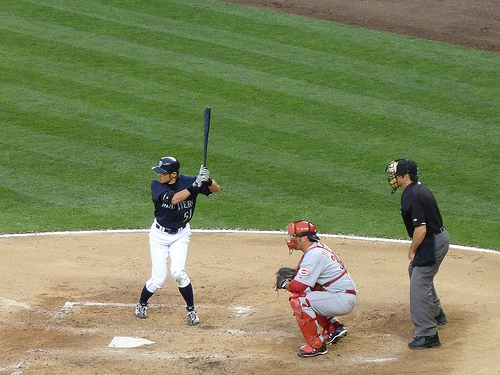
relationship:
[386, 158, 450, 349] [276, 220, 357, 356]
umpire standing behind catcher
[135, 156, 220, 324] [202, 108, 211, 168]
batter holding bat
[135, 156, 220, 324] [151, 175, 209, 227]
batter wearing shirt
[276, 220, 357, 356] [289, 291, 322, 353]
catcher wearing pad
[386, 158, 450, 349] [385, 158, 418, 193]
umpire has a helmet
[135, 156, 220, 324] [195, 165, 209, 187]
batter wearing gloves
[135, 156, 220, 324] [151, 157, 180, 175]
batter wearing helmet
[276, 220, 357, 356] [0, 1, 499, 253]
catcher crouching on field